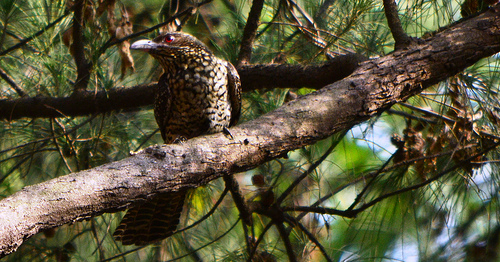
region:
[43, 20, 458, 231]
A bird is perched in a tree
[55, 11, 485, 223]
A bird is looking for prey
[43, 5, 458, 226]
A bird is hunting for a meal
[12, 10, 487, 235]
A bird is watching for predators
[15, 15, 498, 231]
A bird is out in the daytime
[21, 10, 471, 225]
A bird is hunting in the daylight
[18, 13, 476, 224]
The bird is watching for cats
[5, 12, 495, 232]
The bird is looking for a mate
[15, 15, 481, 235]
The bird is in its natural habitat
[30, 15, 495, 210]
The bird has bright red eyes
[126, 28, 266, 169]
bird on the log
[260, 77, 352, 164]
tree branch on the tree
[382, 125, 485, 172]
pinecones on the tree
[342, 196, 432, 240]
green needles of the pine tree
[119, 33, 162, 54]
beak of the bird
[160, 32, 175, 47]
eye of the bird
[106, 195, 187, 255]
feathers on the bird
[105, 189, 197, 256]
tail of the bird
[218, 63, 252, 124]
right wing on the bird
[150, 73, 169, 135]
left wing on the bird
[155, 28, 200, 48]
Bright red eye of bird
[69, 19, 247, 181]
Bird on the tree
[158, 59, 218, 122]
Multicolored feathers on a bird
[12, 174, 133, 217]
Browm branch of a tree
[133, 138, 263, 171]
Browm branch of a tree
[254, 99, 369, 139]
Browm branch of a tree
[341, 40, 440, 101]
Browm branch of a tree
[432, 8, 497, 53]
Browm branch of a tree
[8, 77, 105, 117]
Browm branch of a tree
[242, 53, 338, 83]
Browm branch of a tree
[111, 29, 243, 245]
bird sitting on branch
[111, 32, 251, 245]
bird with grey and brown feathers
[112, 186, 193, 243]
tail of a bird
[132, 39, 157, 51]
beak of a bird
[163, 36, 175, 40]
red eye of a bird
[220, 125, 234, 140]
claw of a bird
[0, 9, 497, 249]
branch with bird on it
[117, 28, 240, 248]
bird sitting on a branch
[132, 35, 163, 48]
beak of a bird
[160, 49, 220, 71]
neck of a bird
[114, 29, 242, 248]
a bird in a tree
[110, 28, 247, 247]
a bird sitting on a tree branch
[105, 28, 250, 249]
a bird looking to the left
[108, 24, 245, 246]
a speckled bird with a red eye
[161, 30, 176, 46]
a red bird eye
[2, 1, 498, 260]
branches of a pine tree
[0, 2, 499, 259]
pine needles and branches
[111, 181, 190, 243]
striped tail feathers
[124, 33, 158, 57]
the bird's beak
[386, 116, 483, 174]
small pine cones